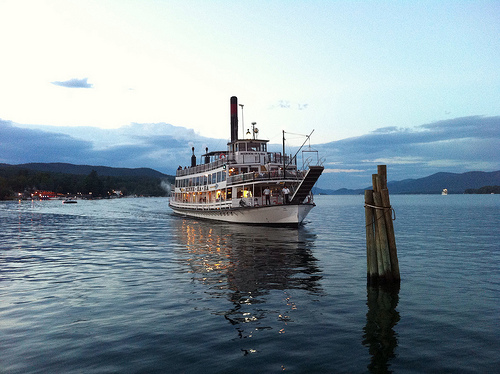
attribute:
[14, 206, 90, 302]
waters — calm, patch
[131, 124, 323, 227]
boat — reflecting, white, passenger, triple decker, ferry, reflected, large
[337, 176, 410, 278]
post — wooden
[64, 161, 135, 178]
mountain — tall, dark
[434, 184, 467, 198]
object — white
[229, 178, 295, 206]
people — standing, working, uniform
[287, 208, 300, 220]
light — on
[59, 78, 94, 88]
clouds — white, dark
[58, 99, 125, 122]
sun — set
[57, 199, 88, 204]
station — docking